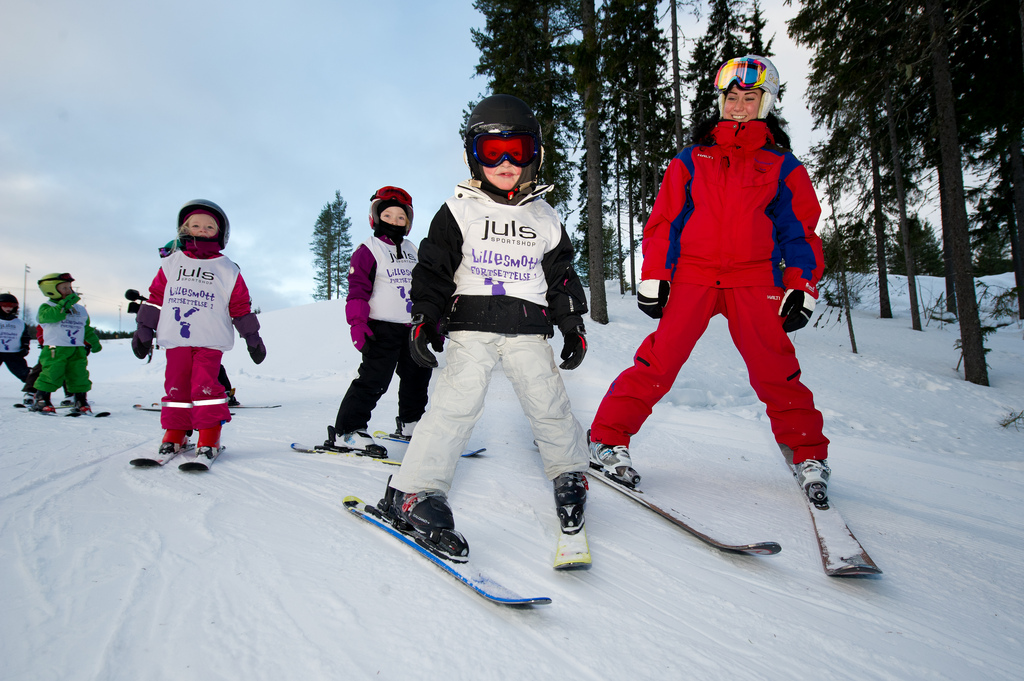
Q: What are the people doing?
A: Taking a ski lesson.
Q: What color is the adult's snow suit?
A: Red and blue.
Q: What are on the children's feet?
A: Skis.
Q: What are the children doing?
A: The children are skiing.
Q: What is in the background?
A: Trees.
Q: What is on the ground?
A: Snow.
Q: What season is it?
A: Winter.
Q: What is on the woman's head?
A: A helmet.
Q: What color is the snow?
A: White.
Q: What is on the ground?
A: Snow.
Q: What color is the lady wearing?
A: Red and blue.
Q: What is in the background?
A: Trees.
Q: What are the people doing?
A: Skiing.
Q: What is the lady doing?
A: Smiling.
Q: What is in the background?
A: Trees.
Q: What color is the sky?
A: Gray.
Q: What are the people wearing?
A: Skis.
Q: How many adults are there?
A: One.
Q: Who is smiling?
A: The woman.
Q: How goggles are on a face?
A: One.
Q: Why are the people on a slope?
A: Ski.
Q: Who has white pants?
A: The child in front.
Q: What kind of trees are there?
A: Evergreen.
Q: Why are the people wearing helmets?
A: Safety.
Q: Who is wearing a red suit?
A: The woman.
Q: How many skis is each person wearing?
A: 2.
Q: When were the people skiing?
A: Winter day.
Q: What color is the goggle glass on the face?
A: Red.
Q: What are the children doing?
A: Learning to ski.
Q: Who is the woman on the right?
A: The instructor.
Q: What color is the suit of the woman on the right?
A: Red.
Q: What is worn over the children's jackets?
A: Vests.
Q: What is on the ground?
A: Snow.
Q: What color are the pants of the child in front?
A: White.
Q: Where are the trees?
A: On the right side.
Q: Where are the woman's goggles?
A: On her helmet.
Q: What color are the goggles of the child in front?
A: Red.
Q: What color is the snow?
A: White.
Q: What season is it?
A: Winter.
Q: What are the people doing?
A: Skiing.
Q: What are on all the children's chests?
A: Vests.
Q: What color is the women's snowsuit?
A: Red and blue.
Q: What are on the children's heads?
A: Helmets.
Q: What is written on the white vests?
A: Juls.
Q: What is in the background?
A: Trees.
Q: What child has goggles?
A: The child in the white pants.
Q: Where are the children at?
A: Ski resort.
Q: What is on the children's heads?
A: Helmets.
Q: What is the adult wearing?
A: Red and blue.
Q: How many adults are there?
A: One.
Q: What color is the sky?
A: Blue.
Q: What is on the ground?
A: Snow.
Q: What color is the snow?
A: White.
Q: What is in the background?
A: Trees.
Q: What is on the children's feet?
A: Skis.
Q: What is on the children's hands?
A: Gloves.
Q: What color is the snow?
A: White.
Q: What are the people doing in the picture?
A: Skiing.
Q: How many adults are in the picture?
A: One.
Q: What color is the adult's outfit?
A: Red.